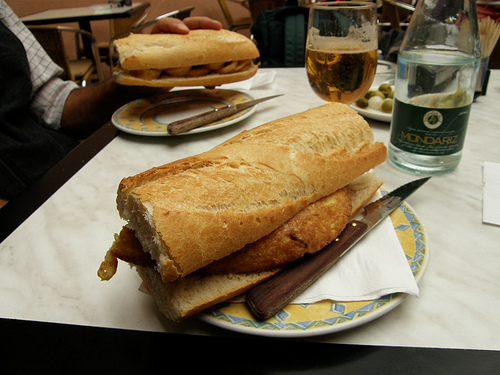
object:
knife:
[165, 90, 286, 136]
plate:
[108, 85, 259, 138]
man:
[0, 0, 221, 207]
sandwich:
[109, 23, 259, 89]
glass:
[303, 0, 379, 105]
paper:
[14, 64, 495, 332]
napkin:
[309, 215, 421, 302]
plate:
[199, 194, 429, 347]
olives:
[358, 82, 398, 117]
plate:
[350, 86, 399, 127]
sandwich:
[95, 102, 390, 325]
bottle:
[388, 4, 481, 175]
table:
[9, 50, 482, 372]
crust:
[244, 133, 344, 198]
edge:
[326, 282, 423, 338]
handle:
[239, 223, 365, 322]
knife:
[243, 176, 433, 318]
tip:
[405, 174, 429, 188]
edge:
[109, 52, 156, 89]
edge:
[380, 219, 424, 298]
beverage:
[304, 45, 378, 106]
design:
[225, 91, 244, 125]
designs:
[196, 89, 247, 128]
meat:
[255, 184, 353, 283]